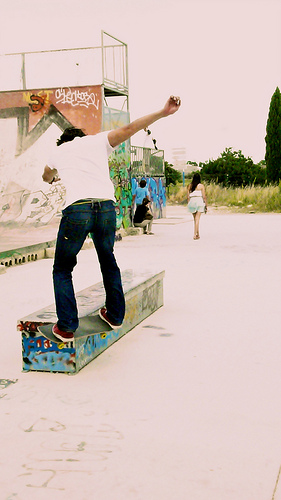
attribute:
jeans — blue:
[51, 199, 124, 333]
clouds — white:
[134, 26, 239, 86]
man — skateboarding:
[42, 94, 182, 342]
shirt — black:
[130, 202, 152, 223]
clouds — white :
[183, 27, 225, 49]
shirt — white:
[184, 186, 209, 197]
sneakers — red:
[52, 324, 75, 341]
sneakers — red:
[98, 306, 121, 328]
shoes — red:
[50, 296, 116, 348]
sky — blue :
[3, 1, 278, 162]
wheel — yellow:
[54, 340, 64, 349]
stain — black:
[149, 321, 160, 329]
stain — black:
[154, 332, 171, 337]